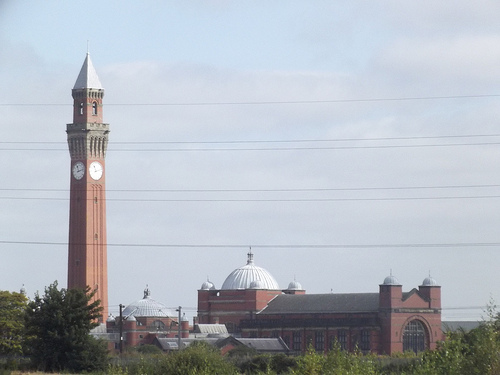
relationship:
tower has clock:
[57, 41, 116, 330] [71, 163, 109, 179]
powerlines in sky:
[13, 107, 499, 252] [1, 3, 474, 272]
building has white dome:
[192, 242, 300, 334] [202, 246, 296, 295]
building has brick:
[192, 242, 300, 334] [218, 304, 236, 310]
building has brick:
[118, 315, 193, 344] [125, 321, 136, 328]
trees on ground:
[5, 290, 94, 374] [5, 353, 499, 374]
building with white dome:
[118, 315, 193, 344] [121, 297, 174, 315]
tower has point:
[57, 41, 116, 330] [74, 42, 101, 91]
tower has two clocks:
[57, 41, 116, 330] [68, 161, 107, 178]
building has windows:
[247, 274, 456, 357] [295, 332, 378, 356]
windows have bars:
[295, 332, 378, 356] [363, 334, 368, 347]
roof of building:
[148, 330, 294, 358] [151, 333, 287, 374]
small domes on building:
[377, 273, 451, 289] [247, 274, 456, 357]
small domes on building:
[202, 275, 307, 292] [192, 242, 300, 334]